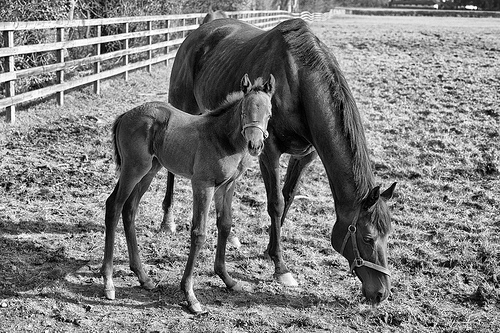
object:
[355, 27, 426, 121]
grass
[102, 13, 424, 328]
horses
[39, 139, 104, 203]
grass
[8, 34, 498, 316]
grass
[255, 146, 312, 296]
legs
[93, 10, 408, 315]
grass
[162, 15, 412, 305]
horse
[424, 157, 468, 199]
grass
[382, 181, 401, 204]
ear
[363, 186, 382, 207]
ear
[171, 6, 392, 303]
horse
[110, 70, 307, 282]
pony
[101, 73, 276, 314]
skinny horse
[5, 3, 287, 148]
fencing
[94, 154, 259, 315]
legs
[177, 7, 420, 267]
horse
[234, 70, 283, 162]
head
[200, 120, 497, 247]
mare eating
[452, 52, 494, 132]
grass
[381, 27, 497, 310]
field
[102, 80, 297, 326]
horse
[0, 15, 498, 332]
grass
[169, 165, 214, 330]
horse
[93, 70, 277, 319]
pony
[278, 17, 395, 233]
mane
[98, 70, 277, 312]
horse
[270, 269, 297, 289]
hoof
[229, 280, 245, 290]
hoof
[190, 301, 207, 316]
hoof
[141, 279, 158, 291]
hoof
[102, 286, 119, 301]
hoof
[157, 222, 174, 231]
hoof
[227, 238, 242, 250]
hoof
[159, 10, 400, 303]
mare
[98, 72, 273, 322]
foal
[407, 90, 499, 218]
grass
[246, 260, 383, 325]
grass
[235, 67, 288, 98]
ears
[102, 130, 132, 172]
tail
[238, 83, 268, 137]
halter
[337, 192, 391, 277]
halter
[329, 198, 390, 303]
head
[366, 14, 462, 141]
grass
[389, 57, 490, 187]
grass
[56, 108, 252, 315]
foal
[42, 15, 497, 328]
area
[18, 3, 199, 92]
fence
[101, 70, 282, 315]
colt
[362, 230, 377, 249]
eye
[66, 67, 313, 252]
foal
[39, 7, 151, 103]
fenced area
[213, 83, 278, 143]
head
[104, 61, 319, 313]
pony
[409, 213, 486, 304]
grass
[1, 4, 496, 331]
fenced area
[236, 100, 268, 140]
halter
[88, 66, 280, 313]
foal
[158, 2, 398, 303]
mother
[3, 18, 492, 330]
field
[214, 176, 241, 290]
leg